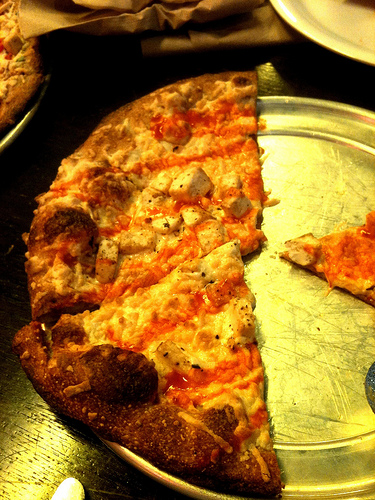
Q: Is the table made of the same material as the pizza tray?
A: No, the table is made of wood and the pizza tray is made of metal.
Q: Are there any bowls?
A: No, there are no bowls.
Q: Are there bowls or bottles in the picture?
A: No, there are no bowls or bottles.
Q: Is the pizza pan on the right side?
A: Yes, the pizza pan is on the right of the image.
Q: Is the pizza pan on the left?
A: No, the pizza pan is on the right of the image.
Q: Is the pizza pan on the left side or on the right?
A: The pizza pan is on the right of the image.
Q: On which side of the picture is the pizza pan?
A: The pizza pan is on the right of the image.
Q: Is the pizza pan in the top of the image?
A: Yes, the pizza pan is in the top of the image.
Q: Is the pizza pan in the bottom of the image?
A: No, the pizza pan is in the top of the image.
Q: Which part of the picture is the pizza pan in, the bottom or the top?
A: The pizza pan is in the top of the image.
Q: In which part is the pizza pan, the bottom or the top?
A: The pizza pan is in the top of the image.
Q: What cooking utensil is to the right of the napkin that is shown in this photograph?
A: The cooking utensil is a pizza pan.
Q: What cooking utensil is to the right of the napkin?
A: The cooking utensil is a pizza pan.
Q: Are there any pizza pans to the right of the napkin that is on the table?
A: Yes, there is a pizza pan to the right of the napkin.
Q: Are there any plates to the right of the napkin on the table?
A: No, there is a pizza pan to the right of the napkin.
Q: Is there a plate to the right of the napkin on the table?
A: No, there is a pizza pan to the right of the napkin.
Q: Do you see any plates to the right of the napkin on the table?
A: No, there is a pizza pan to the right of the napkin.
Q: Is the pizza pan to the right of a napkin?
A: Yes, the pizza pan is to the right of a napkin.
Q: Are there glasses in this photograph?
A: No, there are no glasses.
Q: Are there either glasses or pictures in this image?
A: No, there are no glasses or pictures.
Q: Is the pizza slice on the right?
A: Yes, the pizza slice is on the right of the image.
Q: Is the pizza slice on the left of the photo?
A: No, the pizza slice is on the right of the image.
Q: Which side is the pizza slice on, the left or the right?
A: The pizza slice is on the right of the image.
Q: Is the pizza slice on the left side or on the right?
A: The pizza slice is on the right of the image.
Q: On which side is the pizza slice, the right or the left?
A: The pizza slice is on the right of the image.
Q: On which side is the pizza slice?
A: The pizza slice is on the right of the image.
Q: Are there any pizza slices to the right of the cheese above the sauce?
A: Yes, there is a pizza slice to the right of the cheese.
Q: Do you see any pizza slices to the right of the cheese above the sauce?
A: Yes, there is a pizza slice to the right of the cheese.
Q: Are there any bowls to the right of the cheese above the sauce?
A: No, there is a pizza slice to the right of the cheese.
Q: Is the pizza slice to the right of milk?
A: No, the pizza slice is to the right of the cheese.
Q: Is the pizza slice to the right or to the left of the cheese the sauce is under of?
A: The pizza slice is to the right of the cheese.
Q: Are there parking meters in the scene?
A: No, there are no parking meters.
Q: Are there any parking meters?
A: No, there are no parking meters.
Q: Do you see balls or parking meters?
A: No, there are no parking meters or balls.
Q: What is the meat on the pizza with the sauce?
A: The meat is chicken.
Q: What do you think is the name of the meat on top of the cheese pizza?
A: The meat is chicken.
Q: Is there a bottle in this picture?
A: No, there are no bottles.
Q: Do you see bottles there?
A: No, there are no bottles.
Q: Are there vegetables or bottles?
A: No, there are no bottles or vegetables.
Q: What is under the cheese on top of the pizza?
A: The sauce is under the cheese.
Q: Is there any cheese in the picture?
A: Yes, there is cheese.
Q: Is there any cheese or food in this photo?
A: Yes, there is cheese.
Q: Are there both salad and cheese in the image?
A: No, there is cheese but no salad.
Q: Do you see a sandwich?
A: No, there are no sandwiches.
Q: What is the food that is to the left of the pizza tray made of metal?
A: The food is cheese.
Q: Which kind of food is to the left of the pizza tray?
A: The food is cheese.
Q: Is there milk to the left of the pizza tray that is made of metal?
A: No, there is cheese to the left of the pizza tray.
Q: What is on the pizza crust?
A: The cheese is on the crust.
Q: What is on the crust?
A: The cheese is on the crust.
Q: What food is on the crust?
A: The food is cheese.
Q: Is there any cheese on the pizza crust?
A: Yes, there is cheese on the crust.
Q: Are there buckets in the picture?
A: No, there are no buckets.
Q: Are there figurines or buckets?
A: No, there are no buckets or figurines.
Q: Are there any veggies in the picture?
A: No, there are no veggies.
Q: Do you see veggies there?
A: No, there are no veggies.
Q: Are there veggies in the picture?
A: No, there are no veggies.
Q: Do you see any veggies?
A: No, there are no veggies.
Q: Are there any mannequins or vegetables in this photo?
A: No, there are no vegetables or mannequins.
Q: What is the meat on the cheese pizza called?
A: The meat is chicken.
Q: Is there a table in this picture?
A: Yes, there is a table.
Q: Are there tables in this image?
A: Yes, there is a table.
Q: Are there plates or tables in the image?
A: Yes, there is a table.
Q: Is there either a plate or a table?
A: Yes, there is a table.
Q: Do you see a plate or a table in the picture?
A: Yes, there is a table.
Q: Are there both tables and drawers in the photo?
A: No, there is a table but no drawers.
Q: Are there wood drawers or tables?
A: Yes, there is a wood table.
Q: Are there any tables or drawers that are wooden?
A: Yes, the table is wooden.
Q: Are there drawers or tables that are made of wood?
A: Yes, the table is made of wood.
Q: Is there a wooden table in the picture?
A: Yes, there is a wood table.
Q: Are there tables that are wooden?
A: Yes, there is a table that is wooden.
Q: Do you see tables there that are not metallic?
A: Yes, there is a wooden table.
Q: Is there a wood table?
A: Yes, there is a table that is made of wood.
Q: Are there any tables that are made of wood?
A: Yes, there is a table that is made of wood.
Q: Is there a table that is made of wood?
A: Yes, there is a table that is made of wood.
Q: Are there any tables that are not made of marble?
A: Yes, there is a table that is made of wood.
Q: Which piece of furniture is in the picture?
A: The piece of furniture is a table.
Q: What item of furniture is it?
A: The piece of furniture is a table.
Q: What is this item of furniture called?
A: This is a table.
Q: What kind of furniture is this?
A: This is a table.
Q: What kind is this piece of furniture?
A: This is a table.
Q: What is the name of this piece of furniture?
A: This is a table.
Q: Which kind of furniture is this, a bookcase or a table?
A: This is a table.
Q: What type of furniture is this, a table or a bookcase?
A: This is a table.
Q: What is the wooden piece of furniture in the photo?
A: The piece of furniture is a table.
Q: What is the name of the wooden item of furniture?
A: The piece of furniture is a table.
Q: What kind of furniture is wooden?
A: The furniture is a table.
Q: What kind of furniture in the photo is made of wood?
A: The furniture is a table.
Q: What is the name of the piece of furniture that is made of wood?
A: The piece of furniture is a table.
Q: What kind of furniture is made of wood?
A: The furniture is a table.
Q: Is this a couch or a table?
A: This is a table.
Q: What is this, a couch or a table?
A: This is a table.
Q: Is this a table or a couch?
A: This is a table.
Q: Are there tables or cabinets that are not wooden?
A: No, there is a table but it is wooden.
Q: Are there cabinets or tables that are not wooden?
A: No, there is a table but it is wooden.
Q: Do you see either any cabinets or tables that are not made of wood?
A: No, there is a table but it is made of wood.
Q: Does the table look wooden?
A: Yes, the table is wooden.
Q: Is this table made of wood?
A: Yes, the table is made of wood.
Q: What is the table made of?
A: The table is made of wood.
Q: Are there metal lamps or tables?
A: No, there is a table but it is wooden.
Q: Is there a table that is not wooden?
A: No, there is a table but it is wooden.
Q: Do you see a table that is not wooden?
A: No, there is a table but it is wooden.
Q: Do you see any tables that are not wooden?
A: No, there is a table but it is wooden.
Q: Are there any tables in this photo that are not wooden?
A: No, there is a table but it is wooden.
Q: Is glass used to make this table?
A: No, the table is made of wood.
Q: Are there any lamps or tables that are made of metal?
A: No, there is a table but it is made of wood.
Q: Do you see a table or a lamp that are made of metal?
A: No, there is a table but it is made of wood.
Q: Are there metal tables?
A: No, there is a table but it is made of wood.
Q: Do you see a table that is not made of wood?
A: No, there is a table but it is made of wood.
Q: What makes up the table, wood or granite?
A: The table is made of wood.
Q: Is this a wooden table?
A: Yes, this is a wooden table.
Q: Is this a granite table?
A: No, this is a wooden table.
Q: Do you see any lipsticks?
A: No, there are no lipsticks.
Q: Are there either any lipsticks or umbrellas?
A: No, there are no lipsticks or umbrellas.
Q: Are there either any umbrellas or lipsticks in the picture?
A: No, there are no lipsticks or umbrellas.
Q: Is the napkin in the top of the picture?
A: Yes, the napkin is in the top of the image.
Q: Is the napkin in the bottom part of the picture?
A: No, the napkin is in the top of the image.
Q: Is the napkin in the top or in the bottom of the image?
A: The napkin is in the top of the image.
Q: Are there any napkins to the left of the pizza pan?
A: Yes, there is a napkin to the left of the pizza pan.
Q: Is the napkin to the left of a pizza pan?
A: Yes, the napkin is to the left of a pizza pan.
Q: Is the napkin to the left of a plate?
A: No, the napkin is to the left of a pizza pan.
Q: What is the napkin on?
A: The napkin is on the table.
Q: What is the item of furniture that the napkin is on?
A: The piece of furniture is a table.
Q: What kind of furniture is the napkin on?
A: The napkin is on the table.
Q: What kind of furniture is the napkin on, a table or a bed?
A: The napkin is on a table.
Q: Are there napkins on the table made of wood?
A: Yes, there is a napkin on the table.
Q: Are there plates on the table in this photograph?
A: No, there is a napkin on the table.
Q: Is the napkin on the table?
A: Yes, the napkin is on the table.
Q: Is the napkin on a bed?
A: No, the napkin is on the table.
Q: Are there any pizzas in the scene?
A: Yes, there is a pizza.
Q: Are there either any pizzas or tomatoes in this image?
A: Yes, there is a pizza.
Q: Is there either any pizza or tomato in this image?
A: Yes, there is a pizza.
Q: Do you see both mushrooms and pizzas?
A: No, there is a pizza but no mushrooms.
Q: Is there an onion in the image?
A: No, there are no onions.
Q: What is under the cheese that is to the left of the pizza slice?
A: The sauce is under the cheese.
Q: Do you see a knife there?
A: Yes, there is a knife.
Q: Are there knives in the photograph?
A: Yes, there is a knife.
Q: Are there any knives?
A: Yes, there is a knife.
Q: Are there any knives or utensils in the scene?
A: Yes, there is a knife.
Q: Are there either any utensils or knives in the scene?
A: Yes, there is a knife.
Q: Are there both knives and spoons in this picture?
A: No, there is a knife but no spoons.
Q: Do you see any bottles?
A: No, there are no bottles.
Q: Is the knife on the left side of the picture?
A: Yes, the knife is on the left of the image.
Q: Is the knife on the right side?
A: No, the knife is on the left of the image.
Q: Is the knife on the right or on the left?
A: The knife is on the left of the image.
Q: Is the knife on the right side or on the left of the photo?
A: The knife is on the left of the image.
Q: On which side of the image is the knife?
A: The knife is on the left of the image.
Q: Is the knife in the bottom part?
A: Yes, the knife is in the bottom of the image.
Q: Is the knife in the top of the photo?
A: No, the knife is in the bottom of the image.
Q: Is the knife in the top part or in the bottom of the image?
A: The knife is in the bottom of the image.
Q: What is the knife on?
A: The knife is on the table.